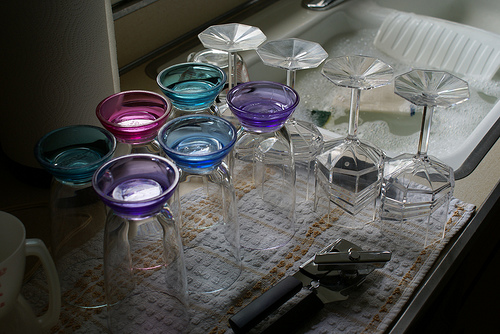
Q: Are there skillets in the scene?
A: No, there are no skillets.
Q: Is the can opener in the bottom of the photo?
A: Yes, the can opener is in the bottom of the image.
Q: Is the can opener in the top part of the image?
A: No, the can opener is in the bottom of the image.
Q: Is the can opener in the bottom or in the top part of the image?
A: The can opener is in the bottom of the image.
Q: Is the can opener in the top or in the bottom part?
A: The can opener is in the bottom of the image.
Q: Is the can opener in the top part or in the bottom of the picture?
A: The can opener is in the bottom of the image.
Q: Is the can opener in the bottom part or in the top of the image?
A: The can opener is in the bottom of the image.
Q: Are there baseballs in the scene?
A: No, there are no baseballs.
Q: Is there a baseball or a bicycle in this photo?
A: No, there are no baseballs or bicycles.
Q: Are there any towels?
A: Yes, there is a towel.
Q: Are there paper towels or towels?
A: Yes, there is a towel.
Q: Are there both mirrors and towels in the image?
A: No, there is a towel but no mirrors.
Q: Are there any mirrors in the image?
A: No, there are no mirrors.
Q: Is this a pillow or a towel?
A: This is a towel.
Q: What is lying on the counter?
A: The towel is lying on the counter.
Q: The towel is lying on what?
A: The towel is lying on the counter.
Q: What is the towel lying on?
A: The towel is lying on the counter.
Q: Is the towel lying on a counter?
A: Yes, the towel is lying on a counter.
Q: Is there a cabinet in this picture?
A: No, there are no cabinets.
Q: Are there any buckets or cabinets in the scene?
A: No, there are no cabinets or buckets.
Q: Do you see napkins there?
A: No, there are no napkins.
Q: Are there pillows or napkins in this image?
A: No, there are no napkins or pillows.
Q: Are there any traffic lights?
A: No, there are no traffic lights.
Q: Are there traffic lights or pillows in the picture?
A: No, there are no traffic lights or pillows.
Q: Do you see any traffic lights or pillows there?
A: No, there are no traffic lights or pillows.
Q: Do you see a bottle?
A: No, there are no bottles.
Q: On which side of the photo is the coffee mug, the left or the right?
A: The coffee mug is on the left of the image.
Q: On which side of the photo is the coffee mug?
A: The coffee mug is on the left of the image.